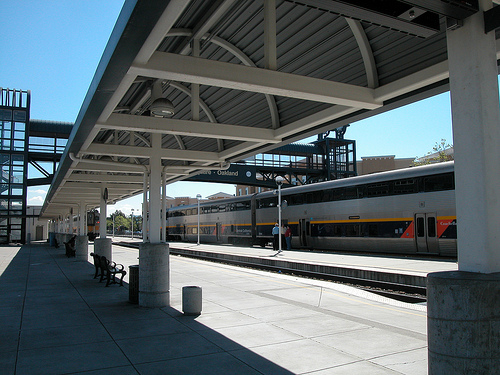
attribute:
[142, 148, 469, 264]
train — silver, here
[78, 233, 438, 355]
boarding platform — here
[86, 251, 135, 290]
bench — metal, empty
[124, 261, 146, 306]
trash can — black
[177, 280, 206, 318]
trash can — white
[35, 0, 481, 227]
shelter — overhead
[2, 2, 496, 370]
train station — open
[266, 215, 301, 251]
people — standing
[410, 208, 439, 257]
doors — gray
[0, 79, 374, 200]
walkway — overhead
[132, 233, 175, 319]
base — concrete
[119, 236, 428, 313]
rails — empty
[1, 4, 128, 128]
sky — blue